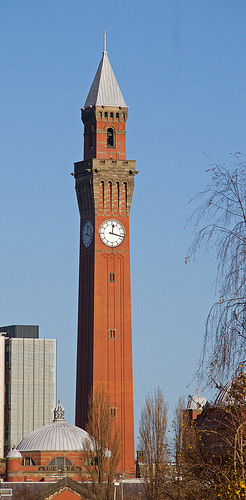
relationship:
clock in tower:
[91, 209, 123, 256] [97, 220, 133, 249]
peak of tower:
[74, 37, 131, 112] [73, 29, 140, 478]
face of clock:
[97, 220, 133, 249] [91, 209, 123, 256]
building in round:
[21, 422, 94, 456] [28, 422, 97, 456]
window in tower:
[96, 122, 119, 153] [97, 220, 133, 249]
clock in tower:
[77, 216, 94, 250] [97, 220, 133, 249]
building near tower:
[3, 326, 58, 420] [97, 220, 133, 249]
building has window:
[21, 422, 94, 456] [96, 122, 119, 153]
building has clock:
[21, 422, 94, 456] [91, 209, 123, 256]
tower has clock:
[97, 220, 133, 249] [91, 209, 123, 256]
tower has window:
[97, 220, 133, 249] [96, 122, 119, 153]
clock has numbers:
[91, 209, 123, 256] [112, 223, 124, 233]